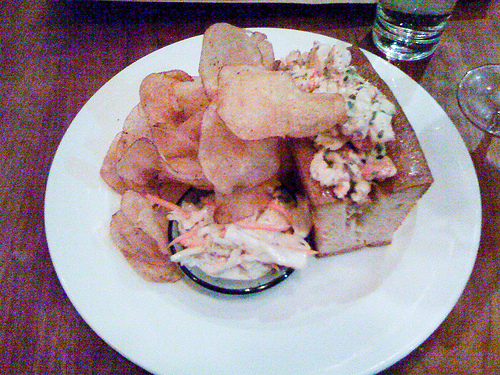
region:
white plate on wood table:
[41, 17, 478, 374]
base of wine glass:
[460, 54, 499, 136]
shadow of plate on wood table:
[434, 147, 498, 374]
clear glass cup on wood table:
[371, 6, 458, 65]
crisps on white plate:
[100, 19, 337, 289]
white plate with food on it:
[39, 25, 484, 373]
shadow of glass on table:
[355, 30, 430, 75]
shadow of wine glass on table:
[465, 122, 499, 162]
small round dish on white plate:
[162, 190, 299, 294]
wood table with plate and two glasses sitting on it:
[3, 2, 497, 364]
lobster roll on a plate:
[272, 44, 430, 253]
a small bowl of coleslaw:
[167, 190, 307, 292]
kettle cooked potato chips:
[102, 30, 344, 283]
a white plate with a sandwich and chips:
[44, 25, 480, 374]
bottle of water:
[374, 3, 454, 60]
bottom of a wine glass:
[457, 60, 498, 135]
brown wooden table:
[3, 3, 497, 373]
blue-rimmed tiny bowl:
[168, 185, 300, 295]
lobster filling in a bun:
[275, 43, 432, 255]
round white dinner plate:
[47, 25, 479, 373]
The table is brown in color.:
[24, 36, 81, 93]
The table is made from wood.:
[33, 21, 81, 94]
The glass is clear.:
[372, 5, 444, 58]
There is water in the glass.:
[373, 3, 453, 57]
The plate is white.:
[306, 307, 378, 354]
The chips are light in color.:
[161, 82, 288, 140]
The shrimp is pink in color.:
[308, 146, 335, 184]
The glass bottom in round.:
[456, 57, 497, 132]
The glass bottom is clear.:
[456, 57, 498, 133]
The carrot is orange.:
[146, 188, 184, 213]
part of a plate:
[420, 269, 430, 270]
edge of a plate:
[402, 289, 414, 304]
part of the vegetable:
[238, 231, 249, 256]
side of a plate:
[378, 300, 389, 310]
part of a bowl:
[208, 245, 219, 251]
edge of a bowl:
[162, 313, 185, 336]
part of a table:
[429, 345, 441, 360]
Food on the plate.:
[125, 66, 401, 266]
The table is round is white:
[55, 252, 455, 342]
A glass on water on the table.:
[373, 7, 455, 59]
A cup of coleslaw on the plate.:
[182, 203, 284, 283]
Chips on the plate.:
[143, 107, 255, 169]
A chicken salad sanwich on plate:
[298, 58, 387, 188]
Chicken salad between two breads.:
[334, 98, 391, 200]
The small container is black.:
[169, 224, 284, 304]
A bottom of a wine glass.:
[464, 54, 489, 124]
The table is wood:
[22, 24, 119, 75]